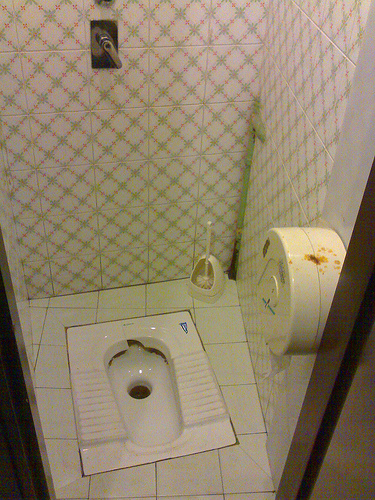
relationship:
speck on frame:
[309, 256, 319, 263] [255, 227, 348, 357]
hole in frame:
[261, 239, 270, 257] [255, 227, 348, 357]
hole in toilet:
[127, 374, 152, 403] [63, 310, 237, 477]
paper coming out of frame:
[268, 353, 293, 376] [255, 227, 348, 357]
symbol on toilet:
[181, 321, 190, 335] [63, 310, 237, 477]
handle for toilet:
[93, 17, 122, 72] [63, 310, 237, 477]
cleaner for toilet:
[188, 220, 224, 302] [63, 310, 237, 477]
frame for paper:
[255, 227, 348, 357] [268, 353, 293, 376]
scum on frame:
[299, 241, 346, 281] [255, 227, 348, 357]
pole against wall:
[228, 97, 261, 283] [0, 1, 272, 295]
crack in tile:
[239, 442, 277, 482] [17, 276, 274, 499]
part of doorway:
[0, 231, 53, 499] [0, 1, 369, 498]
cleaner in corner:
[188, 220, 224, 302] [187, 269, 238, 315]